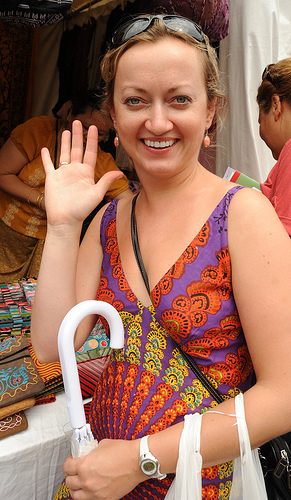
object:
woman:
[30, 12, 289, 498]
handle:
[56, 299, 125, 428]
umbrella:
[57, 298, 125, 463]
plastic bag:
[162, 392, 268, 499]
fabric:
[0, 274, 112, 443]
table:
[1, 392, 72, 498]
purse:
[128, 184, 291, 498]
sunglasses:
[109, 13, 210, 53]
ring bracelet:
[38, 195, 44, 208]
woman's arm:
[0, 114, 47, 206]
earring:
[113, 136, 120, 147]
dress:
[52, 183, 255, 499]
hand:
[41, 119, 123, 225]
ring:
[59, 161, 69, 166]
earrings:
[204, 134, 210, 147]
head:
[103, 13, 220, 179]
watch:
[138, 434, 165, 482]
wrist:
[128, 430, 167, 487]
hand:
[62, 437, 137, 499]